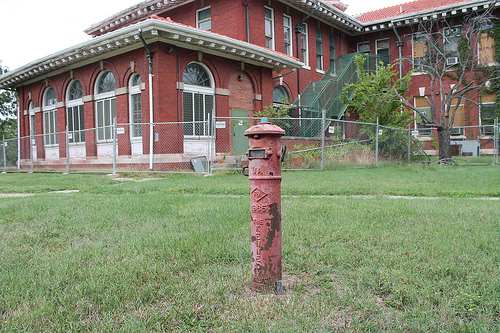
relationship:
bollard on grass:
[243, 116, 288, 294] [133, 211, 389, 331]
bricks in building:
[153, 71, 176, 127] [4, 1, 482, 160]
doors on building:
[17, 64, 147, 165] [4, 1, 482, 160]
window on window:
[475, 14, 497, 66] [473, 14, 498, 68]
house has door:
[4, 11, 327, 160] [175, 56, 220, 161]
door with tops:
[181, 60, 217, 154] [180, 67, 216, 81]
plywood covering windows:
[409, 34, 431, 64] [407, 35, 433, 76]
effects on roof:
[137, 19, 187, 40] [4, 9, 483, 68]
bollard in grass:
[243, 116, 288, 294] [10, 167, 480, 330]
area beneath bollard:
[9, 168, 484, 324] [243, 116, 288, 294]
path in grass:
[0, 188, 500, 202] [10, 167, 480, 330]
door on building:
[231, 105, 252, 162] [4, 1, 482, 160]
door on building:
[181, 60, 217, 154] [4, 1, 482, 160]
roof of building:
[0, 0, 500, 87] [4, 1, 482, 160]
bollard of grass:
[243, 116, 288, 294] [10, 167, 480, 330]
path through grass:
[0, 188, 500, 202] [6, 184, 482, 330]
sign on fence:
[413, 80, 428, 97] [18, 110, 481, 165]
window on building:
[263, 3, 275, 52] [1, 1, 497, 174]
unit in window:
[445, 57, 460, 64] [440, 24, 460, 71]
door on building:
[231, 108, 250, 156] [4, 1, 482, 160]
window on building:
[65, 80, 86, 154] [4, 1, 482, 160]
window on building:
[129, 70, 144, 144] [9, 14, 482, 173]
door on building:
[181, 60, 217, 154] [7, 13, 470, 155]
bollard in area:
[243, 116, 288, 294] [0, 168, 499, 331]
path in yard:
[11, 185, 484, 207] [16, 169, 468, 286]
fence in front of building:
[18, 112, 407, 179] [19, 7, 480, 140]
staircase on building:
[272, 52, 391, 138] [4, 1, 482, 160]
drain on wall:
[137, 29, 157, 171] [19, 50, 153, 160]